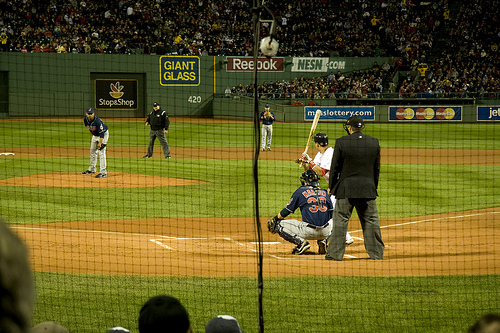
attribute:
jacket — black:
[323, 130, 388, 210]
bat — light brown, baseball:
[296, 100, 325, 172]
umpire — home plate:
[334, 112, 381, 165]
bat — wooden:
[297, 108, 320, 165]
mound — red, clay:
[3, 164, 205, 195]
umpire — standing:
[131, 97, 175, 164]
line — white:
[3, 196, 498, 265]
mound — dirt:
[15, 170, 200, 190]